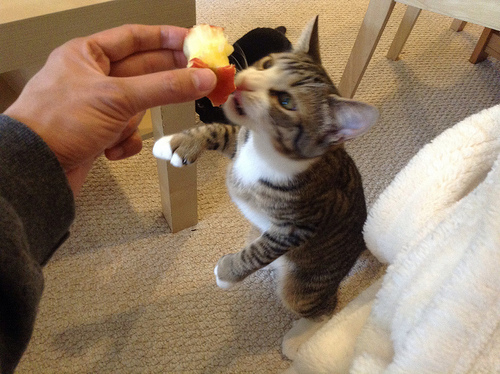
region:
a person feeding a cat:
[0, 4, 385, 325]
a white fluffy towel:
[401, 137, 485, 362]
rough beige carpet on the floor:
[87, 267, 228, 344]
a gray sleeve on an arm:
[6, 132, 78, 324]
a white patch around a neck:
[234, 126, 285, 176]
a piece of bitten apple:
[178, 14, 232, 101]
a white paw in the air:
[156, 135, 188, 162]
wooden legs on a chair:
[361, 2, 418, 68]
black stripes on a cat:
[246, 235, 283, 262]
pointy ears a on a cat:
[305, 19, 372, 138]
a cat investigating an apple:
[145, 23, 370, 324]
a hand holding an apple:
[24, 19, 233, 178]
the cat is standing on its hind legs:
[164, 5, 361, 321]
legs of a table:
[334, 5, 498, 96]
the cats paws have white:
[154, 134, 189, 171]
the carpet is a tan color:
[82, 239, 191, 371]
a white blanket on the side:
[346, 83, 498, 373]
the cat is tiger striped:
[236, 167, 368, 311]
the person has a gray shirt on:
[0, 113, 92, 371]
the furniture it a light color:
[0, 2, 209, 53]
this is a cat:
[233, 42, 352, 311]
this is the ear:
[327, 95, 379, 140]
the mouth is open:
[230, 93, 250, 117]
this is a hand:
[41, 30, 146, 147]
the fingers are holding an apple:
[178, 21, 230, 103]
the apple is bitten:
[194, 27, 232, 61]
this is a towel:
[387, 188, 484, 339]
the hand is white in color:
[47, 75, 126, 122]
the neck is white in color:
[239, 150, 277, 185]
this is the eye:
[275, 87, 298, 110]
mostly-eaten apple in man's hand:
[181, 20, 240, 112]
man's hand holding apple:
[3, 16, 214, 372]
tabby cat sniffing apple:
[148, 14, 376, 370]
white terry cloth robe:
[268, 106, 494, 367]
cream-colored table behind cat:
[3, 1, 203, 248]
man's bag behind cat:
[197, 20, 302, 138]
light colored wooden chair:
[322, 0, 499, 112]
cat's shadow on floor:
[50, 274, 305, 372]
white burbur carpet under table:
[90, 207, 200, 364]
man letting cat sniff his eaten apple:
[3, 14, 377, 371]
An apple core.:
[178, 20, 236, 110]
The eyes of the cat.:
[256, 52, 307, 113]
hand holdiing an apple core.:
[13, 20, 241, 161]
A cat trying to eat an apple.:
[165, 0, 375, 356]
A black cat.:
[205, 11, 296, 61]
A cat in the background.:
[193, 1, 296, 129]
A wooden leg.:
[385, 2, 437, 79]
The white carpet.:
[83, 263, 195, 371]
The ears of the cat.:
[296, 8, 382, 150]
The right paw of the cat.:
[148, 118, 238, 170]